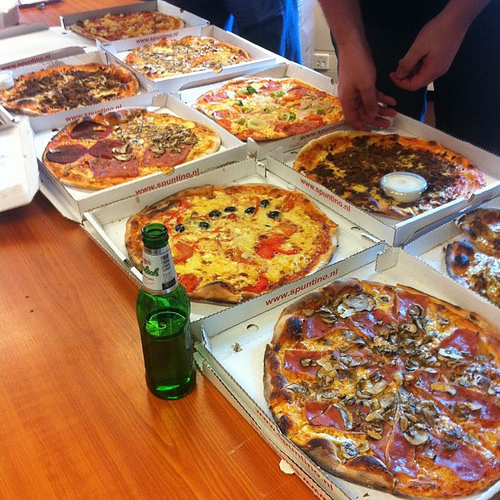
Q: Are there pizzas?
A: Yes, there is a pizza.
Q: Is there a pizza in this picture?
A: Yes, there is a pizza.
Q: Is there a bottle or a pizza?
A: Yes, there is a pizza.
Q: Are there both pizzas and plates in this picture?
A: No, there is a pizza but no plates.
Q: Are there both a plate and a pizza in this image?
A: No, there is a pizza but no plates.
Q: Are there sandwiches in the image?
A: No, there are no sandwiches.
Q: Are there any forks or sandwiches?
A: No, there are no sandwiches or forks.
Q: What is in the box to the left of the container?
A: The pizza is in the box.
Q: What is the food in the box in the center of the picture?
A: The food is a pizza.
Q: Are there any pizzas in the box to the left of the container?
A: Yes, there is a pizza in the box.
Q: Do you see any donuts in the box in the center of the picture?
A: No, there is a pizza in the box.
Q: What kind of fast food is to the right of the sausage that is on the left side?
A: The food is a pizza.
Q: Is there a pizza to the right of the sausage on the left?
A: Yes, there is a pizza to the right of the sausage.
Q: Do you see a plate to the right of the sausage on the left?
A: No, there is a pizza to the right of the sausage.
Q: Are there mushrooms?
A: Yes, there are mushrooms.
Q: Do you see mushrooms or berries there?
A: Yes, there are mushrooms.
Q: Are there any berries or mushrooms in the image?
A: Yes, there are mushrooms.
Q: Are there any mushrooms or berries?
A: Yes, there are mushrooms.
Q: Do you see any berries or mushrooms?
A: Yes, there are mushrooms.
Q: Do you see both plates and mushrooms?
A: No, there are mushrooms but no plates.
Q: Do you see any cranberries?
A: No, there are no cranberries.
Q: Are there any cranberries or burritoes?
A: No, there are no cranberries or burritoes.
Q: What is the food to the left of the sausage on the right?
A: The food is mushrooms.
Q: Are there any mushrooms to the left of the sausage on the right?
A: Yes, there are mushrooms to the left of the sausage.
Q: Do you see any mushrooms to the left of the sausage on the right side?
A: Yes, there are mushrooms to the left of the sausage.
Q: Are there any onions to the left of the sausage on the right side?
A: No, there are mushrooms to the left of the sausage.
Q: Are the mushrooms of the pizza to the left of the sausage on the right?
A: Yes, the mushrooms are to the left of the sausage.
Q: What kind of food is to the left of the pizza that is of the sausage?
A: The food is mushrooms.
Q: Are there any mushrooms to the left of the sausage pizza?
A: Yes, there are mushrooms to the left of the pizza.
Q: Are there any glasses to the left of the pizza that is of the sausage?
A: No, there are mushrooms to the left of the pizza.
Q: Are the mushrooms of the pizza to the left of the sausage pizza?
A: Yes, the mushrooms are to the left of the pizza.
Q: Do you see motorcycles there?
A: No, there are no motorcycles.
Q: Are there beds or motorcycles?
A: No, there are no motorcycles or beds.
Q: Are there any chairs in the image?
A: No, there are no chairs.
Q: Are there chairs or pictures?
A: No, there are no chairs or pictures.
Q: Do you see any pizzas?
A: Yes, there is a pizza.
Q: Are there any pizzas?
A: Yes, there is a pizza.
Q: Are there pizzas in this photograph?
A: Yes, there is a pizza.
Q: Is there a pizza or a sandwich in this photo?
A: Yes, there is a pizza.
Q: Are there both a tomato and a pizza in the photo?
A: Yes, there are both a pizza and a tomato.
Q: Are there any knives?
A: No, there are no knives.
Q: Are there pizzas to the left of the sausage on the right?
A: Yes, there is a pizza to the left of the sausage.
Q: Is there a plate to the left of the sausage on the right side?
A: No, there is a pizza to the left of the sausage.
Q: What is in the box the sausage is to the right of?
A: The pizza is in the box.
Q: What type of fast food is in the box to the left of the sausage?
A: The food is a pizza.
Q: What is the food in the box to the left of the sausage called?
A: The food is a pizza.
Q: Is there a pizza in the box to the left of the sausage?
A: Yes, there is a pizza in the box.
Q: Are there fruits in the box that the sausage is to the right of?
A: No, there is a pizza in the box.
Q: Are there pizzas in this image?
A: Yes, there is a pizza.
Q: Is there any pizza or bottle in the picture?
A: Yes, there is a pizza.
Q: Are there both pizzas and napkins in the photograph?
A: No, there is a pizza but no napkins.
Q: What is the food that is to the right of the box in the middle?
A: The food is a pizza.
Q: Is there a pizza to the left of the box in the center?
A: No, the pizza is to the right of the box.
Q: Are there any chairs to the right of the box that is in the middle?
A: No, there is a pizza to the right of the box.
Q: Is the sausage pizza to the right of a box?
A: Yes, the pizza is to the right of a box.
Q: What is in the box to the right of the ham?
A: The pizza is in the box.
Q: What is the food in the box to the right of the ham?
A: The food is a pizza.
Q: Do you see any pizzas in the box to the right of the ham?
A: Yes, there is a pizza in the box.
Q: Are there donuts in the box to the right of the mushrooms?
A: No, there is a pizza in the box.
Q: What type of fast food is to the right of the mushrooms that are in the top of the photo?
A: The food is a pizza.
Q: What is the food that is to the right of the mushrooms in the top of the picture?
A: The food is a pizza.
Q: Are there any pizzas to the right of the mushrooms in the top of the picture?
A: Yes, there is a pizza to the right of the mushrooms.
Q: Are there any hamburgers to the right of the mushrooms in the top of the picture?
A: No, there is a pizza to the right of the mushrooms.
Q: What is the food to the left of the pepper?
A: The food is a sausage.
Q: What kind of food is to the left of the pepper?
A: The food is a sausage.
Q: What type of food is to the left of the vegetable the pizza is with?
A: The food is a sausage.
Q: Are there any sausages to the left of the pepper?
A: Yes, there is a sausage to the left of the pepper.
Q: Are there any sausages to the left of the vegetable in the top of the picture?
A: Yes, there is a sausage to the left of the pepper.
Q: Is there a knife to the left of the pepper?
A: No, there is a sausage to the left of the pepper.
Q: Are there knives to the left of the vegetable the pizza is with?
A: No, there is a sausage to the left of the pepper.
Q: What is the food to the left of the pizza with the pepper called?
A: The food is a sausage.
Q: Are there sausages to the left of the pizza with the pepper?
A: Yes, there is a sausage to the left of the pizza.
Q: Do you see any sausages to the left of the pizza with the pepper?
A: Yes, there is a sausage to the left of the pizza.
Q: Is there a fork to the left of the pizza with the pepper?
A: No, there is a sausage to the left of the pizza.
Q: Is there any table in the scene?
A: Yes, there is a table.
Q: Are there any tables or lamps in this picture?
A: Yes, there is a table.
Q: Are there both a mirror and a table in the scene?
A: No, there is a table but no mirrors.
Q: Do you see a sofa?
A: No, there are no sofas.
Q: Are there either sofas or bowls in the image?
A: No, there are no sofas or bowls.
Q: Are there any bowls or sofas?
A: No, there are no sofas or bowls.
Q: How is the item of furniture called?
A: The piece of furniture is a table.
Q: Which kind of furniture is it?
A: The piece of furniture is a table.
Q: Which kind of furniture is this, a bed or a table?
A: This is a table.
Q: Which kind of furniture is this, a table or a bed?
A: This is a table.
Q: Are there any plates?
A: No, there are no plates.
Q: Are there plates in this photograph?
A: No, there are no plates.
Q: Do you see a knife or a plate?
A: No, there are no plates or knives.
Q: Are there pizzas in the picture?
A: Yes, there is a pizza.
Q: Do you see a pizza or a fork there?
A: Yes, there is a pizza.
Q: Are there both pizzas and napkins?
A: No, there is a pizza but no napkins.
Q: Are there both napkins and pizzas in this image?
A: No, there is a pizza but no napkins.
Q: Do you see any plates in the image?
A: No, there are no plates.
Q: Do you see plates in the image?
A: No, there are no plates.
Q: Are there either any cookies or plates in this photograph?
A: No, there are no plates or cookies.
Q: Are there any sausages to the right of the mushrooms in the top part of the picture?
A: Yes, there is a sausage to the right of the mushrooms.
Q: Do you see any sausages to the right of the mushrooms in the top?
A: Yes, there is a sausage to the right of the mushrooms.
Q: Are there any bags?
A: No, there are no bags.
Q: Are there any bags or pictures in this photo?
A: No, there are no bags or pictures.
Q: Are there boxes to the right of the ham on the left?
A: Yes, there is a box to the right of the ham.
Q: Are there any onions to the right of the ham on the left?
A: No, there is a box to the right of the ham.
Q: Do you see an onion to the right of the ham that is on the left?
A: No, there is a box to the right of the ham.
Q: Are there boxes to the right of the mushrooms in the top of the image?
A: Yes, there is a box to the right of the mushrooms.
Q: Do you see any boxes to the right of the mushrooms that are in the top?
A: Yes, there is a box to the right of the mushrooms.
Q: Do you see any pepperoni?
A: Yes, there is pepperoni.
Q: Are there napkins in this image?
A: No, there are no napkins.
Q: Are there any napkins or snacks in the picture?
A: No, there are no napkins or snacks.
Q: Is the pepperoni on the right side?
A: Yes, the pepperoni is on the right of the image.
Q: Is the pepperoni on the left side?
A: No, the pepperoni is on the right of the image.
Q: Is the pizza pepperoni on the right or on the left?
A: The pepperoni is on the right of the image.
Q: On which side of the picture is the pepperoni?
A: The pepperoni is on the right of the image.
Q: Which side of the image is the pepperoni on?
A: The pepperoni is on the right of the image.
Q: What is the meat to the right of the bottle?
A: The meat is pepperoni.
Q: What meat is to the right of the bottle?
A: The meat is pepperoni.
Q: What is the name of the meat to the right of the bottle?
A: The meat is pepperoni.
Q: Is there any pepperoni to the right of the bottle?
A: Yes, there is pepperoni to the right of the bottle.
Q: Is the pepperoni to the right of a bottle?
A: Yes, the pepperoni is to the right of a bottle.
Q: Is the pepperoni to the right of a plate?
A: No, the pepperoni is to the right of a bottle.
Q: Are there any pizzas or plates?
A: Yes, there is a pizza.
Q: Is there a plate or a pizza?
A: Yes, there is a pizza.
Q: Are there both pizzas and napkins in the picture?
A: No, there is a pizza but no napkins.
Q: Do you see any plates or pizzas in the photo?
A: Yes, there is a pizza.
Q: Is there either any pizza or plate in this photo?
A: Yes, there is a pizza.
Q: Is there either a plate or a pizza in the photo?
A: Yes, there is a pizza.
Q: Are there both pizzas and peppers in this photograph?
A: Yes, there are both a pizza and a pepper.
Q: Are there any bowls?
A: No, there are no bowls.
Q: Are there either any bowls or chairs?
A: No, there are no bowls or chairs.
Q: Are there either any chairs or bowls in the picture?
A: No, there are no bowls or chairs.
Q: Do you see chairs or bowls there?
A: No, there are no bowls or chairs.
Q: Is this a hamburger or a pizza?
A: This is a pizza.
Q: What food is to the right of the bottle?
A: The food is a pizza.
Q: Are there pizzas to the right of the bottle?
A: Yes, there is a pizza to the right of the bottle.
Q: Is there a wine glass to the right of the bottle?
A: No, there is a pizza to the right of the bottle.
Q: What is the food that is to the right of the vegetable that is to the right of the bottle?
A: The food is a pizza.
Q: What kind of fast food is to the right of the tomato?
A: The food is a pizza.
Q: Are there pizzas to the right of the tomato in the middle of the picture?
A: Yes, there is a pizza to the right of the tomato.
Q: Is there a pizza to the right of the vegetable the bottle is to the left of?
A: Yes, there is a pizza to the right of the tomato.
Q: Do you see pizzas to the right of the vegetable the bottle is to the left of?
A: Yes, there is a pizza to the right of the tomato.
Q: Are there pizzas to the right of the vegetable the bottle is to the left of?
A: Yes, there is a pizza to the right of the tomato.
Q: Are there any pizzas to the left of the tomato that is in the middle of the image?
A: No, the pizza is to the right of the tomato.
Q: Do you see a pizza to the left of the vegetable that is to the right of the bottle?
A: No, the pizza is to the right of the tomato.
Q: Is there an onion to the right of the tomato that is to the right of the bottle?
A: No, there is a pizza to the right of the tomato.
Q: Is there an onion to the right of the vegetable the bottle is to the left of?
A: No, there is a pizza to the right of the tomato.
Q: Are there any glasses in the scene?
A: No, there are no glasses.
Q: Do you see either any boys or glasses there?
A: No, there are no glasses or boys.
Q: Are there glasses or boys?
A: No, there are no glasses or boys.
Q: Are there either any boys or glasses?
A: No, there are no glasses or boys.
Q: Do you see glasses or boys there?
A: No, there are no glasses or boys.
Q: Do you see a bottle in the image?
A: Yes, there is a bottle.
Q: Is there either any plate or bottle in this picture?
A: Yes, there is a bottle.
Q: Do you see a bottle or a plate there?
A: Yes, there is a bottle.